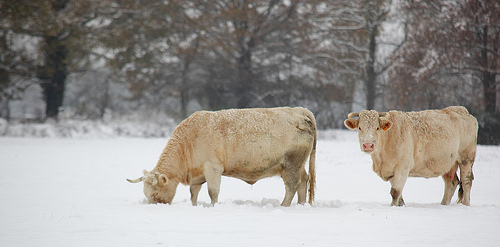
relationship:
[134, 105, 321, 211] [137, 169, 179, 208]
cow has face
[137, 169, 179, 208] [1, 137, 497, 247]
face in snow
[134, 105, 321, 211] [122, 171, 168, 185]
cow has horns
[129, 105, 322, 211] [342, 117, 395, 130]
cow have ears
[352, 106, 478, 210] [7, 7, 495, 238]
cow looking at camera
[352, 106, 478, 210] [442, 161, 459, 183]
cow has udder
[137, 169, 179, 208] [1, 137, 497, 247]
face under snow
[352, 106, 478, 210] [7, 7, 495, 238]
cow staring at camera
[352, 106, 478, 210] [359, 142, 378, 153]
cow has nose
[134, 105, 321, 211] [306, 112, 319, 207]
cow has tail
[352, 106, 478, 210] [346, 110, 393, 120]
cow has horns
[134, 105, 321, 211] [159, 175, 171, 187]
cow has ear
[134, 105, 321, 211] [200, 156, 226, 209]
cow has left front leg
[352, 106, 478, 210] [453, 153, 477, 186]
cow has patches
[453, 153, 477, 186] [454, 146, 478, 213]
patches on left hind leg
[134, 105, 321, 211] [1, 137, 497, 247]
cow standing in snow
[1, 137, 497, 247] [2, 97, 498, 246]
snow covering field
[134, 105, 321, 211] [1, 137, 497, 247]
cow grazing in snow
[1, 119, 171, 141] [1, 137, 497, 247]
bushes covered in snow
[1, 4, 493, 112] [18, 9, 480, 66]
trees with sparse leaves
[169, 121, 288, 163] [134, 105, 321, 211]
hair in side of cow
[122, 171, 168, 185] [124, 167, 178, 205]
horns on cow's head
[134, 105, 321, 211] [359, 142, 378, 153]
cow has nose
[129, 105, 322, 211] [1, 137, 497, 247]
cow in snow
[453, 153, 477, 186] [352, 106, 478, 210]
patches on side of cow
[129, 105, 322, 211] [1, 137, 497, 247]
cow standing in snow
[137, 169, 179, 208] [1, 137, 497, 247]
face deep in snow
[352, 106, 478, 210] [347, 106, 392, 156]
cow with head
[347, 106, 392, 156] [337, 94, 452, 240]
head turned to left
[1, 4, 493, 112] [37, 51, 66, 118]
trees with trunks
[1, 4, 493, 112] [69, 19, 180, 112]
trees have branches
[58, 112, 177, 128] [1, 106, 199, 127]
foilage at tree base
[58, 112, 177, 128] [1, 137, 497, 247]
foilage covered in snow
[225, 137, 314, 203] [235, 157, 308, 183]
belly has marks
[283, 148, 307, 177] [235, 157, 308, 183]
thighs have marks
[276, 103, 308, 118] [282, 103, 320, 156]
bump on rump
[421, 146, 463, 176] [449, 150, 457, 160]
belly bottom has point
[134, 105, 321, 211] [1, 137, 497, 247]
cow in snow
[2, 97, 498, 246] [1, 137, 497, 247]
field covered in snow